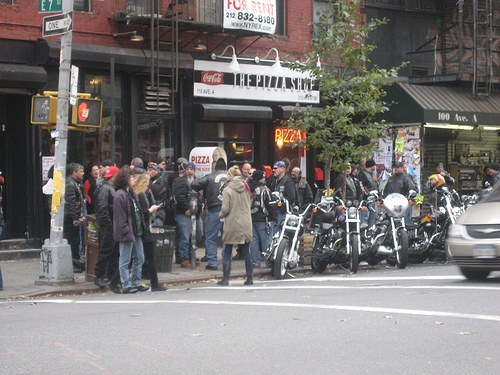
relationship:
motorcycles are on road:
[257, 186, 481, 270] [8, 260, 500, 371]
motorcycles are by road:
[257, 186, 481, 270] [8, 260, 500, 371]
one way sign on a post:
[35, 11, 83, 37] [37, 2, 76, 291]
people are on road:
[65, 153, 499, 283] [8, 260, 500, 371]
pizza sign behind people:
[184, 144, 226, 177] [65, 153, 499, 283]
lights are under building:
[217, 41, 329, 81] [1, 0, 378, 200]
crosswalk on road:
[74, 284, 500, 327] [8, 260, 500, 371]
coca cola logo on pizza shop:
[199, 68, 226, 91] [234, 73, 316, 92]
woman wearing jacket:
[214, 164, 263, 288] [225, 181, 257, 243]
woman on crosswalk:
[214, 164, 263, 288] [74, 284, 500, 327]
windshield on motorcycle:
[285, 203, 309, 223] [263, 188, 325, 279]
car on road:
[442, 172, 499, 290] [8, 260, 500, 371]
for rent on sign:
[223, 0, 280, 18] [220, 0, 283, 43]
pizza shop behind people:
[170, 2, 342, 202] [65, 153, 499, 283]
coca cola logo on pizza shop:
[199, 68, 226, 91] [170, 2, 342, 202]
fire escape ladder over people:
[142, 1, 189, 124] [65, 153, 499, 283]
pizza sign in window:
[269, 123, 308, 153] [269, 126, 323, 182]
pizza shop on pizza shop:
[227, 66, 319, 99] [234, 73, 316, 92]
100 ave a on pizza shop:
[195, 82, 223, 103] [234, 73, 316, 92]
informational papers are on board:
[371, 130, 418, 181] [360, 120, 428, 208]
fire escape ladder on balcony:
[142, 1, 189, 124] [111, 2, 295, 37]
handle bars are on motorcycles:
[265, 186, 470, 222] [257, 186, 481, 270]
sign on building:
[220, 0, 283, 43] [1, 0, 378, 200]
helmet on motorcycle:
[379, 193, 411, 218] [364, 183, 421, 272]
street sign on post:
[34, 0, 73, 16] [37, 2, 76, 291]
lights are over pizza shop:
[217, 41, 329, 81] [234, 73, 316, 92]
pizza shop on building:
[234, 73, 316, 92] [1, 0, 378, 200]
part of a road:
[206, 306, 315, 354] [8, 260, 500, 371]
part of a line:
[254, 297, 299, 310] [24, 293, 497, 324]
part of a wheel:
[351, 247, 356, 261] [266, 235, 303, 282]